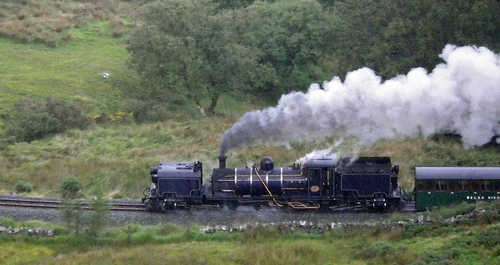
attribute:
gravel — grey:
[118, 207, 228, 223]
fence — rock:
[2, 217, 479, 226]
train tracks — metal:
[0, 191, 144, 216]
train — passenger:
[149, 147, 497, 230]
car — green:
[412, 164, 497, 215]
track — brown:
[21, 172, 146, 223]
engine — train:
[212, 147, 402, 210]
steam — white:
[238, 49, 490, 146]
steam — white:
[293, 42, 498, 164]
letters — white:
[465, 190, 498, 204]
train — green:
[123, 140, 495, 216]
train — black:
[97, 142, 494, 222]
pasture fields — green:
[12, 139, 140, 189]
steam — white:
[61, 188, 120, 200]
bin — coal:
[346, 143, 411, 222]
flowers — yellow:
[88, 106, 135, 123]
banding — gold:
[214, 168, 307, 189]